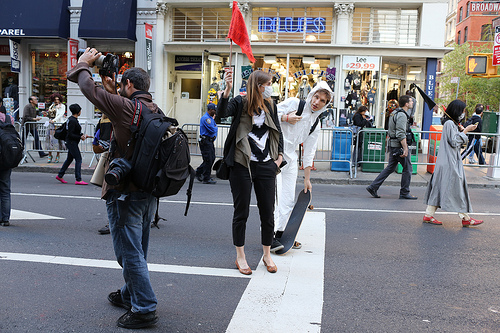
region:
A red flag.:
[227, 3, 259, 65]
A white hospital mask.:
[254, 80, 271, 99]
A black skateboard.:
[269, 186, 314, 256]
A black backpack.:
[118, 92, 199, 214]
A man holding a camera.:
[64, 42, 196, 330]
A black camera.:
[97, 157, 132, 190]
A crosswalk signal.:
[467, 56, 489, 76]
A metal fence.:
[3, 117, 498, 176]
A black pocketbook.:
[49, 120, 70, 140]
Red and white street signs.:
[493, 31, 498, 68]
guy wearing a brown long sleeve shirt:
[65, 40, 201, 330]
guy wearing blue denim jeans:
[65, 41, 205, 331]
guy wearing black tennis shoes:
[66, 40, 207, 330]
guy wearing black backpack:
[54, 38, 208, 330]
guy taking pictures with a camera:
[48, 26, 213, 330]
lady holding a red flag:
[202, 3, 294, 287]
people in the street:
[0, 2, 488, 330]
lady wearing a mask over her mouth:
[195, 0, 299, 281]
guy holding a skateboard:
[271, 63, 342, 262]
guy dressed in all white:
[271, 73, 337, 255]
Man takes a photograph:
[64, 47, 196, 328]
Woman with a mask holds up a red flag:
[214, 1, 284, 276]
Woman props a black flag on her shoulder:
[414, 84, 484, 229]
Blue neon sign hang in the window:
[255, 16, 326, 36]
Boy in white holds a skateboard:
[275, 80, 334, 255]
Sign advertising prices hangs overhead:
[340, 54, 380, 73]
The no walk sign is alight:
[463, 52, 495, 76]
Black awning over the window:
[76, 0, 138, 44]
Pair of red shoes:
[420, 212, 485, 229]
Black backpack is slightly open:
[117, 113, 195, 228]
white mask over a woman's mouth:
[259, 84, 274, 99]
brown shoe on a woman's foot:
[230, 256, 252, 275]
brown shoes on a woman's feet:
[233, 248, 278, 275]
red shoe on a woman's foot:
[420, 213, 443, 225]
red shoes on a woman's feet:
[420, 213, 486, 228]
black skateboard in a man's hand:
[274, 187, 316, 257]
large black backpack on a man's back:
[124, 95, 199, 213]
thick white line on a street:
[0, 245, 255, 279]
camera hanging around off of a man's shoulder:
[102, 97, 144, 189]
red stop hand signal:
[467, 56, 477, 72]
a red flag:
[228, 3, 260, 66]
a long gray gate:
[355, 129, 499, 180]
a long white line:
[314, 199, 499, 231]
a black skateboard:
[270, 186, 317, 256]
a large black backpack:
[128, 99, 195, 203]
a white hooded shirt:
[272, 77, 339, 174]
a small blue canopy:
[75, 0, 136, 40]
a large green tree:
[435, 41, 497, 106]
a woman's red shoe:
[420, 213, 440, 223]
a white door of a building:
[180, 69, 210, 130]